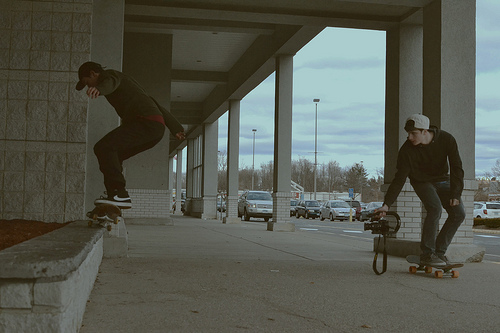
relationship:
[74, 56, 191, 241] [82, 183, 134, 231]
skater performing trick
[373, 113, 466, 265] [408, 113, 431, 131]
boy wearing white hat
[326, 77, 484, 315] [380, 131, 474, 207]
boy wearing sweatshirt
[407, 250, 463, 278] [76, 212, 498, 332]
skateboard on sidewalk